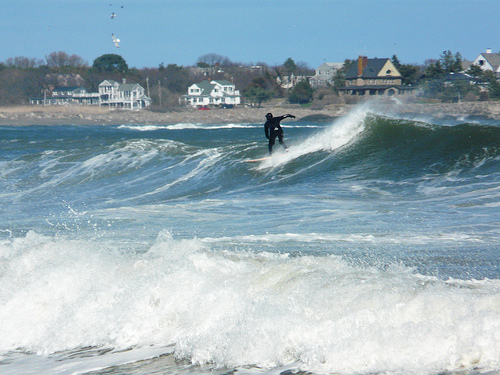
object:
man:
[264, 112, 296, 157]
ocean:
[0, 104, 499, 374]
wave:
[0, 99, 500, 203]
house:
[179, 79, 242, 110]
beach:
[0, 99, 497, 128]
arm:
[280, 114, 295, 121]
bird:
[112, 34, 120, 48]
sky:
[0, 2, 500, 68]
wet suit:
[263, 113, 295, 155]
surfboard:
[244, 157, 275, 163]